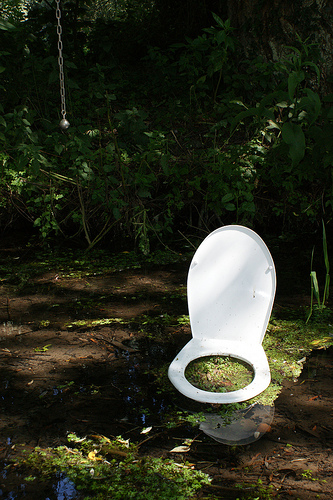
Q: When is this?
A: Daytime.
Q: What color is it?
A: White.